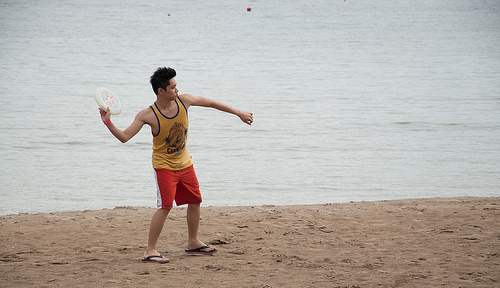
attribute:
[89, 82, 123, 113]
frisbee — white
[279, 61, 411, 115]
water — blue, green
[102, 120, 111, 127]
band — red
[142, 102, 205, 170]
tank top — black, yellow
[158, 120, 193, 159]
design — black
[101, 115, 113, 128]
bracelet — orange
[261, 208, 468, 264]
shore — covered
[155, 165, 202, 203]
shorts — white, red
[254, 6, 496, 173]
waters — behind, calm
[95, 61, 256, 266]
man — standing, wearing, throwing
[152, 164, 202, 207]
short — striped, red, white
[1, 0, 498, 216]
water — calm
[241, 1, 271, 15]
ball — red, little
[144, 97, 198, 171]
shirt — yellow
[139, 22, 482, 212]
water field — peaceful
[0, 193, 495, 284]
sand — tan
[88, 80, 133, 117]
frisbee — white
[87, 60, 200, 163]
man — holding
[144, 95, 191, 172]
shirt — yellow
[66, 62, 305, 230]
man — WITH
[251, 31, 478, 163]
water — calm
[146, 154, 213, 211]
shorts — red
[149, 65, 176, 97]
hair — black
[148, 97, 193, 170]
tank top — yellow